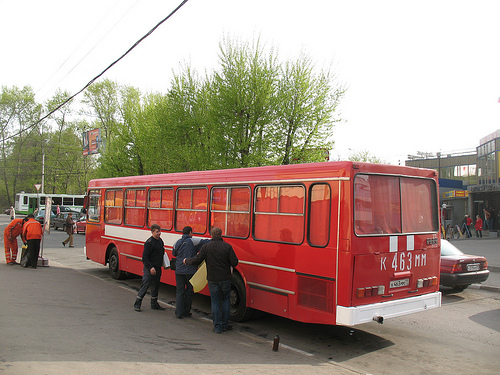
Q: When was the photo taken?
A: Day time.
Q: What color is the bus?
A: Red.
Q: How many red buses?
A: One.